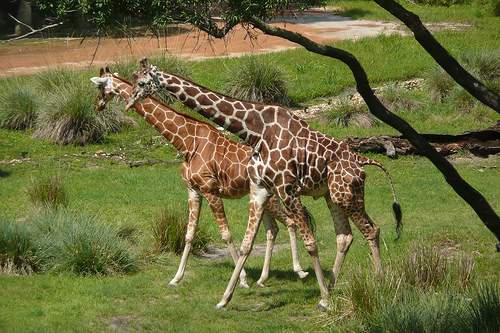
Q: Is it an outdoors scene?
A: Yes, it is outdoors.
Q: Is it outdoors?
A: Yes, it is outdoors.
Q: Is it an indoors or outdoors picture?
A: It is outdoors.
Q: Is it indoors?
A: No, it is outdoors.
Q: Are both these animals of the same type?
A: Yes, all the animals are giraffes.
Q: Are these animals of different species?
A: No, all the animals are giraffes.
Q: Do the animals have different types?
A: No, all the animals are giraffes.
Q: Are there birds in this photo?
A: No, there are no birds.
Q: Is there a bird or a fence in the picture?
A: No, there are no birds or fences.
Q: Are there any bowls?
A: No, there are no bowls.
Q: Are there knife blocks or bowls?
A: No, there are no bowls or knife blocks.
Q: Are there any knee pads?
A: No, there are no knee pads.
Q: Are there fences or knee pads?
A: No, there are no knee pads or fences.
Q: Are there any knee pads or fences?
A: No, there are no knee pads or fences.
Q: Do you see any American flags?
A: No, there are no American flags.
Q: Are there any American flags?
A: No, there are no American flags.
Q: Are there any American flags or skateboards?
A: No, there are no American flags or skateboards.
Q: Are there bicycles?
A: No, there are no bicycles.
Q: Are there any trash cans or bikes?
A: No, there are no bikes or trash cans.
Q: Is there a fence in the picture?
A: No, there are no fences.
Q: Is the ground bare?
A: Yes, the ground is bare.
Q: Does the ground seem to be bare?
A: Yes, the ground is bare.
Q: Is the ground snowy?
A: No, the ground is bare.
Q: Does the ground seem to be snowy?
A: No, the ground is bare.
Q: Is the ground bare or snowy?
A: The ground is bare.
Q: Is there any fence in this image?
A: No, there are no fences.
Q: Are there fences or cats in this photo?
A: No, there are no fences or cats.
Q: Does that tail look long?
A: Yes, the tail is long.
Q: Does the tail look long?
A: Yes, the tail is long.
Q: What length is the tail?
A: The tail is long.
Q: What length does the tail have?
A: The tail has long length.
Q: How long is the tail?
A: The tail is long.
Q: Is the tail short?
A: No, the tail is long.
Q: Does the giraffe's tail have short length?
A: No, the tail is long.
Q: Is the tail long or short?
A: The tail is long.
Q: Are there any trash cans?
A: No, there are no trash cans.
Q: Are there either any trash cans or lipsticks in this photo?
A: No, there are no trash cans or lipsticks.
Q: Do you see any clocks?
A: No, there are no clocks.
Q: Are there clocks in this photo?
A: No, there are no clocks.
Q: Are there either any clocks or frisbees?
A: No, there are no clocks or frisbees.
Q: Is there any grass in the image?
A: Yes, there is grass.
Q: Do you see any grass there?
A: Yes, there is grass.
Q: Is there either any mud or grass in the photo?
A: Yes, there is grass.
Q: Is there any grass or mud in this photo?
A: Yes, there is grass.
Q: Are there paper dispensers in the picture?
A: No, there are no paper dispensers.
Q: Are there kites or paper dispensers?
A: No, there are no paper dispensers or kites.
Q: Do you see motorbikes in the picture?
A: No, there are no motorbikes.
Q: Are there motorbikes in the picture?
A: No, there are no motorbikes.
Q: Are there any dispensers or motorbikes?
A: No, there are no motorbikes or dispensers.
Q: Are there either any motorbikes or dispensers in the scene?
A: No, there are no motorbikes or dispensers.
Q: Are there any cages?
A: No, there are no cages.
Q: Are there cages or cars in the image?
A: No, there are no cages or cars.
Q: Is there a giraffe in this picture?
A: Yes, there is a giraffe.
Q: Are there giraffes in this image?
A: Yes, there is a giraffe.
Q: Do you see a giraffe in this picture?
A: Yes, there is a giraffe.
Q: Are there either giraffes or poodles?
A: Yes, there is a giraffe.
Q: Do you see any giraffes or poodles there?
A: Yes, there is a giraffe.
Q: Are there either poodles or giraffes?
A: Yes, there is a giraffe.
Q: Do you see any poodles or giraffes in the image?
A: Yes, there is a giraffe.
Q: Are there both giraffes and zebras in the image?
A: No, there is a giraffe but no zebras.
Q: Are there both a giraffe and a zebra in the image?
A: No, there is a giraffe but no zebras.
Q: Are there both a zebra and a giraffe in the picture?
A: No, there is a giraffe but no zebras.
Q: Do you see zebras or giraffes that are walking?
A: Yes, the giraffe is walking.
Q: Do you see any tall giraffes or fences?
A: Yes, there is a tall giraffe.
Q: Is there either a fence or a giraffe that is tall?
A: Yes, the giraffe is tall.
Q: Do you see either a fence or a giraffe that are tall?
A: Yes, the giraffe is tall.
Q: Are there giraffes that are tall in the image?
A: Yes, there is a tall giraffe.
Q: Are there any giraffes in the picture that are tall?
A: Yes, there is a giraffe that is tall.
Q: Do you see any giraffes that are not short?
A: Yes, there is a tall giraffe.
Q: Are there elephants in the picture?
A: No, there are no elephants.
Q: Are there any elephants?
A: No, there are no elephants.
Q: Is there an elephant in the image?
A: No, there are no elephants.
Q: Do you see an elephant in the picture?
A: No, there are no elephants.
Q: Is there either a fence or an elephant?
A: No, there are no elephants or fences.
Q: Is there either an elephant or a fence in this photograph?
A: No, there are no elephants or fences.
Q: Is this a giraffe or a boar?
A: This is a giraffe.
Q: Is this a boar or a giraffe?
A: This is a giraffe.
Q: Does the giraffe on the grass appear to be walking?
A: Yes, the giraffe is walking.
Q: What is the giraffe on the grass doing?
A: The giraffe is walking.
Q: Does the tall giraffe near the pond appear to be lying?
A: No, the giraffe is walking.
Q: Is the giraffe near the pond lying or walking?
A: The giraffe is walking.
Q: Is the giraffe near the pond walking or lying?
A: The giraffe is walking.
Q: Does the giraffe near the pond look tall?
A: Yes, the giraffe is tall.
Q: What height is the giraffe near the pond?
A: The giraffe is tall.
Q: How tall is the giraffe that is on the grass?
A: The giraffe is tall.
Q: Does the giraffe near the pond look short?
A: No, the giraffe is tall.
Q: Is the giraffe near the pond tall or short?
A: The giraffe is tall.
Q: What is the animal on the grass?
A: The animal is a giraffe.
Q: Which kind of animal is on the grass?
A: The animal is a giraffe.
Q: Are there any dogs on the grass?
A: No, there is a giraffe on the grass.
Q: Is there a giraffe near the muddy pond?
A: Yes, there is a giraffe near the pond.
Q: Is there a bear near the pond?
A: No, there is a giraffe near the pond.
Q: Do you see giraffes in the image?
A: Yes, there is a giraffe.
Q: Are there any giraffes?
A: Yes, there is a giraffe.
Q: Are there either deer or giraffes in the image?
A: Yes, there is a giraffe.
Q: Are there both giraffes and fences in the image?
A: No, there is a giraffe but no fences.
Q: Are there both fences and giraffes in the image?
A: No, there is a giraffe but no fences.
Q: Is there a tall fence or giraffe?
A: Yes, there is a tall giraffe.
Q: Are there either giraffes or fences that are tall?
A: Yes, the giraffe is tall.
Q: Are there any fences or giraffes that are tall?
A: Yes, the giraffe is tall.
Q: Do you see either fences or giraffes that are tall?
A: Yes, the giraffe is tall.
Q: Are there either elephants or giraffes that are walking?
A: Yes, the giraffe is walking.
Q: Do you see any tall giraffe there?
A: Yes, there is a tall giraffe.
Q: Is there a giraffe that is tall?
A: Yes, there is a giraffe that is tall.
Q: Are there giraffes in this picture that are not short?
A: Yes, there is a tall giraffe.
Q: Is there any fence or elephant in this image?
A: No, there are no elephants or fences.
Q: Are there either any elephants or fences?
A: No, there are no elephants or fences.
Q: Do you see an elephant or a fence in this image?
A: No, there are no elephants or fences.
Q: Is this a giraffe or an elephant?
A: This is a giraffe.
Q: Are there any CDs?
A: No, there are no cds.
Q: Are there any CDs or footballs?
A: No, there are no CDs or footballs.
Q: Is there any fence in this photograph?
A: No, there are no fences.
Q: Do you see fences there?
A: No, there are no fences.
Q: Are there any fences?
A: No, there are no fences.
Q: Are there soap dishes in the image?
A: No, there are no soap dishes.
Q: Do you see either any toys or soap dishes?
A: No, there are no soap dishes or toys.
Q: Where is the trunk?
A: The trunk is on the grass.